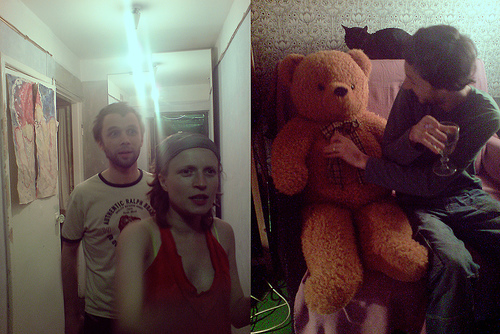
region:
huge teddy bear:
[285, 54, 419, 287]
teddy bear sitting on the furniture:
[281, 85, 406, 242]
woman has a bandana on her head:
[150, 133, 225, 169]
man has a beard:
[90, 141, 127, 163]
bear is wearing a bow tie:
[325, 120, 363, 150]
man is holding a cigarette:
[425, 107, 440, 132]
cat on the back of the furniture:
[320, 18, 420, 60]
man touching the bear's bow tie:
[322, 127, 356, 195]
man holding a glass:
[427, 118, 470, 178]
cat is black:
[351, 13, 419, 62]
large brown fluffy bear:
[273, 46, 413, 306]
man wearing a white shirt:
[49, 92, 166, 324]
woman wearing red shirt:
[110, 128, 277, 331]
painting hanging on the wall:
[7, 71, 63, 210]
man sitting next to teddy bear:
[288, 22, 496, 213]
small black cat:
[337, 19, 419, 64]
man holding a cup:
[382, 29, 494, 206]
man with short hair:
[87, 94, 152, 179]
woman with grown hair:
[139, 128, 219, 230]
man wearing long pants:
[385, 25, 497, 332]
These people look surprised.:
[74, 81, 234, 216]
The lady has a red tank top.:
[155, 223, 234, 324]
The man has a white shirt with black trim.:
[76, 169, 162, 315]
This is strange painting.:
[7, 63, 77, 203]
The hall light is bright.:
[102, 15, 198, 115]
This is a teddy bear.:
[295, 53, 407, 289]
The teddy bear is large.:
[285, 23, 398, 269]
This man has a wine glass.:
[403, 110, 461, 175]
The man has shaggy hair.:
[392, 20, 477, 98]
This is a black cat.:
[341, 24, 412, 64]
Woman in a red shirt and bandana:
[115, 128, 254, 332]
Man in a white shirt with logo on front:
[57, 101, 162, 311]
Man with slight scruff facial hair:
[88, 101, 149, 175]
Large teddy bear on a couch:
[272, 39, 425, 306]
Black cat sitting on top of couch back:
[337, 18, 418, 61]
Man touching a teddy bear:
[378, 26, 498, 331]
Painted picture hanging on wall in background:
[6, 71, 62, 202]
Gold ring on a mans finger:
[329, 145, 339, 152]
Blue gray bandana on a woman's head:
[157, 130, 222, 167]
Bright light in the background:
[117, 16, 147, 41]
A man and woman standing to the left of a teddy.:
[58, 102, 250, 332]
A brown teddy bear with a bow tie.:
[269, 46, 429, 313]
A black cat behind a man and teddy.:
[339, 21, 414, 58]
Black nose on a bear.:
[332, 85, 348, 97]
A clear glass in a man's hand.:
[432, 119, 461, 178]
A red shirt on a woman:
[146, 214, 232, 331]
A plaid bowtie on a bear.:
[320, 117, 369, 187]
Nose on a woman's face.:
[190, 167, 206, 192]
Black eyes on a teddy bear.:
[315, 80, 356, 92]